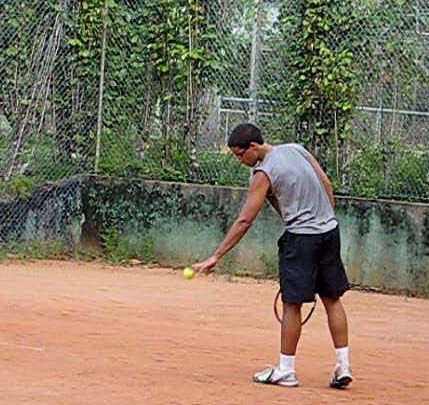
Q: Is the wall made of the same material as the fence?
A: No, the wall is made of concrete and the fence is made of metal.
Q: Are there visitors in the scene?
A: No, there are no visitors.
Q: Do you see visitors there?
A: No, there are no visitors.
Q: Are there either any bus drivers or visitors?
A: No, there are no visitors or bus drivers.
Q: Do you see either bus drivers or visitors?
A: No, there are no visitors or bus drivers.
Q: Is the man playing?
A: Yes, the man is playing.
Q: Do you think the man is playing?
A: Yes, the man is playing.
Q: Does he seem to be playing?
A: Yes, the man is playing.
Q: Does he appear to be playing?
A: Yes, the man is playing.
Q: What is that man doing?
A: The man is playing.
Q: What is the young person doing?
A: The man is playing.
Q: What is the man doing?
A: The man is playing.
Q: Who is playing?
A: The man is playing.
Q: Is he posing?
A: No, the man is playing.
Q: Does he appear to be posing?
A: No, the man is playing.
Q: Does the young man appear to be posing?
A: No, the man is playing.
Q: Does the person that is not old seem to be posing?
A: No, the man is playing.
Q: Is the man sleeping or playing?
A: The man is playing.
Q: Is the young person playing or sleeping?
A: The man is playing.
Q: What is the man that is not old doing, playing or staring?
A: The man is playing.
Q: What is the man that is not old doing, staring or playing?
A: The man is playing.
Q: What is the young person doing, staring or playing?
A: The man is playing.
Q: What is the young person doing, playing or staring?
A: The man is playing.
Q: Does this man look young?
A: Yes, the man is young.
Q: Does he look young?
A: Yes, the man is young.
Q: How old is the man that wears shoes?
A: The man is young.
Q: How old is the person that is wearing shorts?
A: The man is young.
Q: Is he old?
A: No, the man is young.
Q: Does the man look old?
A: No, the man is young.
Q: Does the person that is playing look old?
A: No, the man is young.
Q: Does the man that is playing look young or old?
A: The man is young.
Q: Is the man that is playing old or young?
A: The man is young.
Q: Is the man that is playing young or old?
A: The man is young.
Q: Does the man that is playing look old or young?
A: The man is young.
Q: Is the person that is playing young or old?
A: The man is young.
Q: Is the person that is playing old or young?
A: The man is young.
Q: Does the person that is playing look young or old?
A: The man is young.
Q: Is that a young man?
A: Yes, that is a young man.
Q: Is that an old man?
A: No, that is a young man.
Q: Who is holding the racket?
A: The man is holding the racket.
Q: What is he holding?
A: The man is holding the tennis racket.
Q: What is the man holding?
A: The man is holding the tennis racket.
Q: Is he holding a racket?
A: Yes, the man is holding a racket.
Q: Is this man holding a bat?
A: No, the man is holding a racket.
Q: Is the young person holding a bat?
A: No, the man is holding a racket.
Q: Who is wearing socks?
A: The man is wearing socks.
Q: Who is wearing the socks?
A: The man is wearing socks.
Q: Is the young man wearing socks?
A: Yes, the man is wearing socks.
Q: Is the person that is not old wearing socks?
A: Yes, the man is wearing socks.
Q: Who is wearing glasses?
A: The man is wearing glasses.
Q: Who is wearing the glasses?
A: The man is wearing glasses.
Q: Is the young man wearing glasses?
A: Yes, the man is wearing glasses.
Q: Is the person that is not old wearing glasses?
A: Yes, the man is wearing glasses.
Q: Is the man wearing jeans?
A: No, the man is wearing glasses.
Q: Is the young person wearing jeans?
A: No, the man is wearing glasses.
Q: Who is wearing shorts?
A: The man is wearing shorts.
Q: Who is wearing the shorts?
A: The man is wearing shorts.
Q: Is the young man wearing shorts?
A: Yes, the man is wearing shorts.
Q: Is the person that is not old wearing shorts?
A: Yes, the man is wearing shorts.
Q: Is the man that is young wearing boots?
A: No, the man is wearing shorts.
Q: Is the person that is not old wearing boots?
A: No, the man is wearing shorts.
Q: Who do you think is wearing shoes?
A: The man is wearing shoes.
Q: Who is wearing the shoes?
A: The man is wearing shoes.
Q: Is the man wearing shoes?
A: Yes, the man is wearing shoes.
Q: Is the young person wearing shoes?
A: Yes, the man is wearing shoes.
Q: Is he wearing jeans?
A: No, the man is wearing shoes.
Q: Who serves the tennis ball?
A: The man serves the tennis ball.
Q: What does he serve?
A: The man serves a tennis ball.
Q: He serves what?
A: The man serves a tennis ball.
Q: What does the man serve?
A: The man serves a tennis ball.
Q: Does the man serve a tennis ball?
A: Yes, the man serves a tennis ball.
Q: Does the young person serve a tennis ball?
A: Yes, the man serves a tennis ball.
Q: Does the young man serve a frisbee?
A: No, the man serves a tennis ball.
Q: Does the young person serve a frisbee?
A: No, the man serves a tennis ball.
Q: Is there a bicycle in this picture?
A: No, there are no bicycles.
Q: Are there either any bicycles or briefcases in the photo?
A: No, there are no bicycles or briefcases.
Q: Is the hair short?
A: Yes, the hair is short.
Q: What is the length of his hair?
A: The hair is short.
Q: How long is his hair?
A: The hair is short.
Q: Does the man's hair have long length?
A: No, the hair is short.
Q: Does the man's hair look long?
A: No, the hair is short.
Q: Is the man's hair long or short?
A: The hair is short.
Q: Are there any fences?
A: Yes, there is a fence.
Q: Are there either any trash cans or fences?
A: Yes, there is a fence.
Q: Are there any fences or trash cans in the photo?
A: Yes, there is a fence.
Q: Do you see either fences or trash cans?
A: Yes, there is a fence.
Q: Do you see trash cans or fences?
A: Yes, there is a fence.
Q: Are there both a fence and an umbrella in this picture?
A: No, there is a fence but no umbrellas.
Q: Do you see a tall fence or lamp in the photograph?
A: Yes, there is a tall fence.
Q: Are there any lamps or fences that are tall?
A: Yes, the fence is tall.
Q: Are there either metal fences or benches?
A: Yes, there is a metal fence.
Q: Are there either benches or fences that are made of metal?
A: Yes, the fence is made of metal.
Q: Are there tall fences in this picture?
A: Yes, there is a tall fence.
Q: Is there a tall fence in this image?
A: Yes, there is a tall fence.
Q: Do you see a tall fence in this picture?
A: Yes, there is a tall fence.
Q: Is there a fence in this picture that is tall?
A: Yes, there is a fence that is tall.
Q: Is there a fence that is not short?
A: Yes, there is a tall fence.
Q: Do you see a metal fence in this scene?
A: Yes, there is a fence that is made of metal.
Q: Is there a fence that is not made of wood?
A: Yes, there is a fence that is made of metal.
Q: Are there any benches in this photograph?
A: No, there are no benches.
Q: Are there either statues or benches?
A: No, there are no benches or statues.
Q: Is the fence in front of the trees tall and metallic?
A: Yes, the fence is tall and metallic.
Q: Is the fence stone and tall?
A: No, the fence is tall but metallic.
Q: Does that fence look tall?
A: Yes, the fence is tall.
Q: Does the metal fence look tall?
A: Yes, the fence is tall.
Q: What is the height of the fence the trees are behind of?
A: The fence is tall.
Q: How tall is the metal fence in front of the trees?
A: The fence is tall.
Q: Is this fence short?
A: No, the fence is tall.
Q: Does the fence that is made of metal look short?
A: No, the fence is tall.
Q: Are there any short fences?
A: No, there is a fence but it is tall.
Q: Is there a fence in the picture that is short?
A: No, there is a fence but it is tall.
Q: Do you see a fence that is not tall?
A: No, there is a fence but it is tall.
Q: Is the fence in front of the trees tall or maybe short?
A: The fence is tall.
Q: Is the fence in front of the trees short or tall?
A: The fence is tall.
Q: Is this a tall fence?
A: Yes, this is a tall fence.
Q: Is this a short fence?
A: No, this is a tall fence.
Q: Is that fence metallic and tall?
A: Yes, the fence is metallic and tall.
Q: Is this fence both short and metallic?
A: No, the fence is metallic but tall.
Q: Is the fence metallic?
A: Yes, the fence is metallic.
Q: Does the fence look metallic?
A: Yes, the fence is metallic.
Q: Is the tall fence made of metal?
A: Yes, the fence is made of metal.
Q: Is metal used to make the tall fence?
A: Yes, the fence is made of metal.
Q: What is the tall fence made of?
A: The fence is made of metal.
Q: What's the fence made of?
A: The fence is made of metal.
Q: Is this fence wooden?
A: No, the fence is metallic.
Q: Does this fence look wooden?
A: No, the fence is metallic.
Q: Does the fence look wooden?
A: No, the fence is metallic.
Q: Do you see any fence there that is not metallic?
A: No, there is a fence but it is metallic.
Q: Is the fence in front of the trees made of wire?
A: No, the fence is made of metal.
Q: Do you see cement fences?
A: No, there is a fence but it is made of metal.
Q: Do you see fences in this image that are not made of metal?
A: No, there is a fence but it is made of metal.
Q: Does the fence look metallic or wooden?
A: The fence is metallic.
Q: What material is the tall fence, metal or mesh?
A: The fence is made of metal.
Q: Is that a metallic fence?
A: Yes, that is a metallic fence.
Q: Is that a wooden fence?
A: No, that is a metallic fence.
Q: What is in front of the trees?
A: The fence is in front of the trees.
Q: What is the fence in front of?
A: The fence is in front of the trees.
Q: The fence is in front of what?
A: The fence is in front of the trees.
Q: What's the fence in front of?
A: The fence is in front of the trees.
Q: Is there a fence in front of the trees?
A: Yes, there is a fence in front of the trees.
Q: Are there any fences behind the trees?
A: No, the fence is in front of the trees.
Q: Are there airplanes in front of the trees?
A: No, there is a fence in front of the trees.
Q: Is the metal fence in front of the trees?
A: Yes, the fence is in front of the trees.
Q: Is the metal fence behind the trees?
A: No, the fence is in front of the trees.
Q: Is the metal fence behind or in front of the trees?
A: The fence is in front of the trees.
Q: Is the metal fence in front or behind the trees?
A: The fence is in front of the trees.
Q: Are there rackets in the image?
A: Yes, there is a racket.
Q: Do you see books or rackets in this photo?
A: Yes, there is a racket.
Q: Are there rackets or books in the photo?
A: Yes, there is a racket.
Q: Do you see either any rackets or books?
A: Yes, there is a racket.